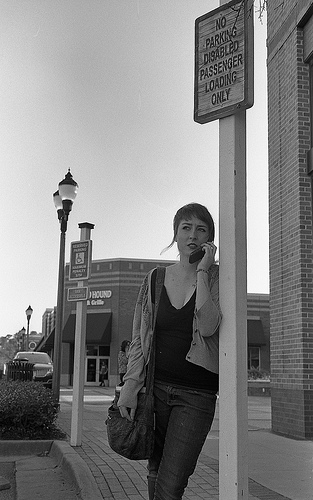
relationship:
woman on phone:
[140, 200, 238, 469] [187, 243, 222, 273]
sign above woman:
[181, 14, 260, 122] [140, 200, 238, 469]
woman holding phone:
[140, 200, 238, 469] [187, 243, 222, 273]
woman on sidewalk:
[140, 200, 238, 469] [55, 431, 147, 496]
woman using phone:
[140, 200, 238, 469] [187, 243, 222, 273]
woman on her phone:
[140, 200, 238, 469] [187, 243, 222, 273]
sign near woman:
[181, 14, 260, 122] [140, 200, 238, 469]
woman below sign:
[140, 200, 238, 469] [181, 14, 260, 122]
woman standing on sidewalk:
[140, 200, 238, 469] [55, 431, 147, 496]